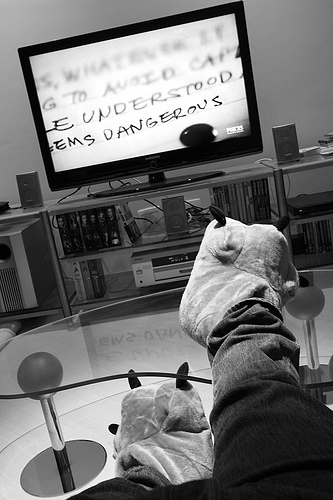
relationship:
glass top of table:
[0, 265, 332, 410] [0, 270, 320, 494]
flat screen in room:
[10, 0, 264, 194] [1, 0, 331, 499]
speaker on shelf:
[161, 196, 191, 238] [59, 211, 254, 263]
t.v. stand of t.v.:
[1, 144, 332, 327] [16, 2, 263, 199]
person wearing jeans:
[82, 199, 332, 500] [196, 305, 278, 396]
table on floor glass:
[3, 267, 175, 382] [100, 315, 149, 349]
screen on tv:
[7, 11, 307, 158] [15, 3, 269, 199]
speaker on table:
[159, 193, 194, 240] [3, 141, 322, 326]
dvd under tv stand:
[210, 177, 274, 225] [0, 186, 332, 321]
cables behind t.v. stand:
[183, 197, 209, 227] [0, 144, 332, 332]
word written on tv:
[92, 91, 227, 141] [18, 8, 273, 156]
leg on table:
[184, 297, 324, 496] [0, 270, 320, 494]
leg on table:
[202, 302, 333, 500] [0, 270, 320, 494]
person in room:
[82, 193, 330, 495] [1, 0, 331, 499]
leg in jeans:
[202, 302, 333, 500] [35, 314, 330, 498]